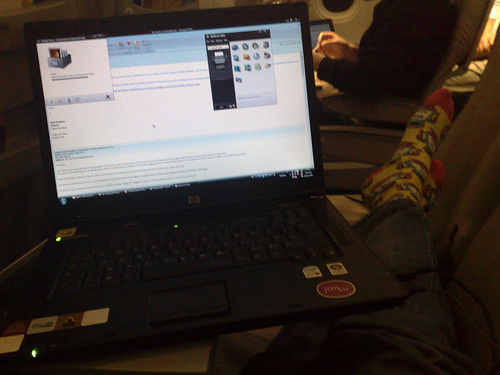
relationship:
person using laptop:
[318, 1, 468, 113] [14, 22, 409, 338]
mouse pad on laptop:
[147, 284, 244, 320] [27, 21, 376, 343]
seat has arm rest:
[284, 21, 498, 372] [304, 108, 405, 135]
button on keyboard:
[56, 205, 337, 295] [30, 166, 401, 331]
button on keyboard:
[233, 234, 248, 251] [11, 204, 411, 370]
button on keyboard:
[56, 205, 337, 295] [47, 205, 361, 290]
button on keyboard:
[56, 205, 337, 295] [33, 184, 394, 354]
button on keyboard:
[56, 205, 337, 295] [60, 205, 325, 282]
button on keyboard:
[56, 205, 337, 295] [35, 224, 322, 275]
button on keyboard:
[56, 205, 337, 295] [46, 203, 344, 296]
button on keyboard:
[56, 205, 337, 295] [105, 209, 315, 274]